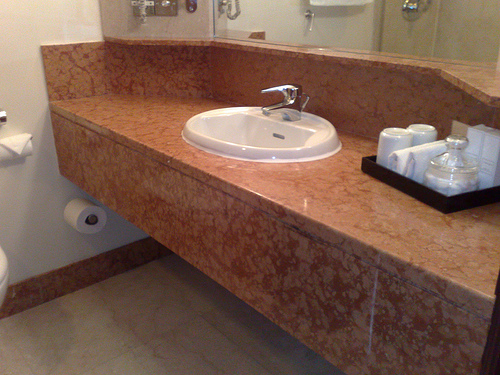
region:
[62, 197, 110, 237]
A toilet roll attached to a wall.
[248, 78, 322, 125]
A glossy faucet next inside a sink.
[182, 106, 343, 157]
A white sink inside the counter.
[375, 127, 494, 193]
Amenities for a restroom.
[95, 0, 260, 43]
The edge of a mirror.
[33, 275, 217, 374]
The tiles on the bottom of the restroom.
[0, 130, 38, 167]
A flip of toilet paper.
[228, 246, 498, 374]
The front half of a marble counter.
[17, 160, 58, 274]
The wall of a restroom.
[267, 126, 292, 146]
The exit hole of the side of the sink.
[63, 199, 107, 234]
a roll of toilet paper under the counter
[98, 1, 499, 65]
the mirror above the counter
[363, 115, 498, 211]
a little tray filled with assorted items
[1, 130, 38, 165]
another of toilet paper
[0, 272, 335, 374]
the floor of the bathroom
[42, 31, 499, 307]
the counter of the sink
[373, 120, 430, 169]
two white cups on the tray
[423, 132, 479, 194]
a glass jar on the shelf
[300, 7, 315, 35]
a handle on the wall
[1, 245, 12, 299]
the edge of a white toilet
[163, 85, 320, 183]
The sink is white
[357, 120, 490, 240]
There are white coffee cups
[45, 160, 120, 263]
There is toilet paper under the counter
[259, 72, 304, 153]
The sink handle is metal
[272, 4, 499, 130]
There is a mirror above the sink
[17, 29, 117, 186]
The wall is white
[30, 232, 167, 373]
The floor is tan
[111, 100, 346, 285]
The sink is reddish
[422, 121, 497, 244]
There is a small jar here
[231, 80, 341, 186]
The sink is off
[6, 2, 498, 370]
a bathroom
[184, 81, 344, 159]
a white sink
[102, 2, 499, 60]
mirror above sink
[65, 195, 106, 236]
toilet paper on a hanger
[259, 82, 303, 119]
a silver faucet on sink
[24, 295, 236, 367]
tiled bathroom floor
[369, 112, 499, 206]
black tray containing toiletries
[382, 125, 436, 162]
white cups inverted on a tray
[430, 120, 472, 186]
a bottle on black tray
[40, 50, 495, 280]
a brown counter top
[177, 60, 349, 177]
White bathroom vanity sink.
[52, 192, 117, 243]
Spare toilet paper location.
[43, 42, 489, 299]
Smooth marble counter top.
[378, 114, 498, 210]
Black bathroom amenities tray.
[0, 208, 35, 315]
Tan bathroom toilet.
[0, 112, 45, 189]
White toilet paper rack location.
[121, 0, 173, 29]
Hairdryer and electric GFI plugin.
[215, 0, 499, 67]
Bathroom vanity mirror.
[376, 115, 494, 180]
Bathroom amenities and spares.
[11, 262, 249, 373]
Stone bathroom tile floors